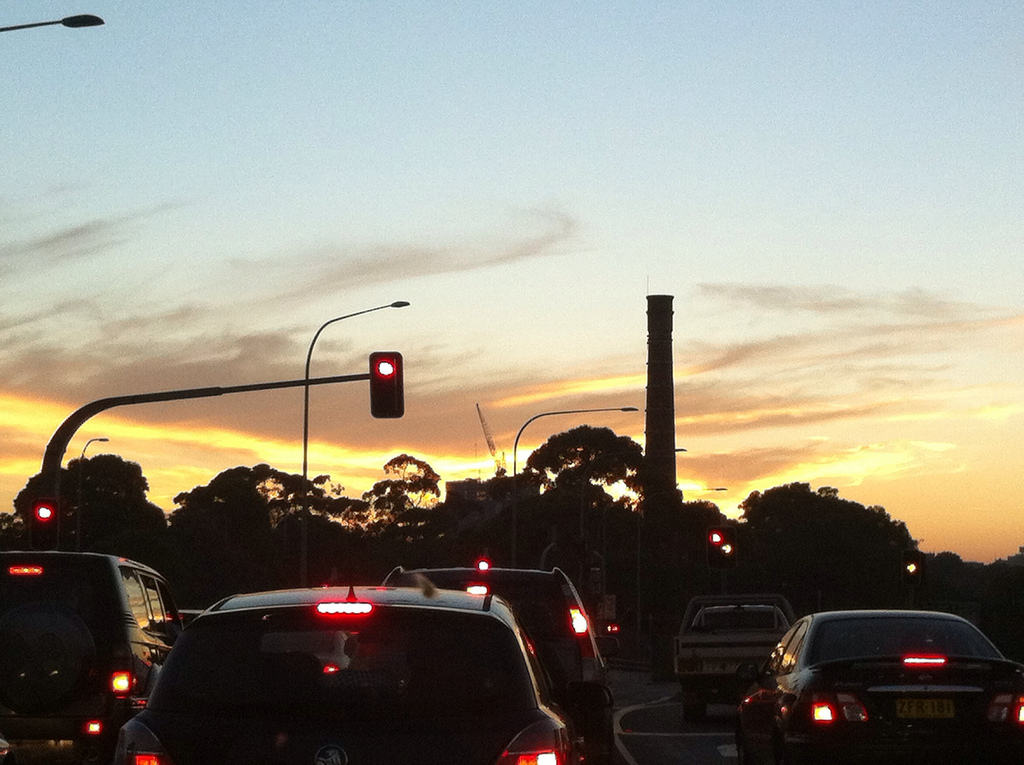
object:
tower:
[643, 295, 678, 661]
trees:
[165, 454, 441, 611]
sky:
[0, 0, 1024, 565]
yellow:
[0, 350, 974, 528]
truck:
[673, 593, 793, 692]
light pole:
[302, 301, 411, 480]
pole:
[41, 350, 405, 502]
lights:
[88, 560, 620, 765]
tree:
[521, 424, 649, 497]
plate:
[895, 699, 955, 718]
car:
[736, 608, 1024, 765]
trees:
[13, 453, 167, 577]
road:
[575, 667, 810, 764]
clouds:
[0, 177, 1024, 499]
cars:
[0, 551, 1024, 765]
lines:
[613, 696, 736, 765]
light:
[901, 657, 948, 663]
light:
[315, 601, 373, 614]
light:
[813, 705, 833, 721]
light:
[570, 608, 587, 634]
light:
[30, 497, 60, 550]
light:
[369, 352, 404, 418]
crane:
[476, 400, 508, 473]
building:
[444, 472, 540, 536]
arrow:
[707, 528, 734, 555]